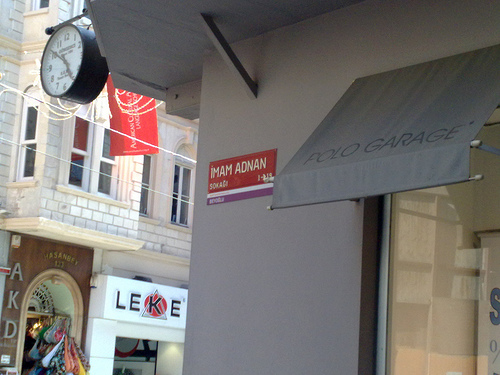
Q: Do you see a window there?
A: Yes, there is a window.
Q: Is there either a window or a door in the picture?
A: Yes, there is a window.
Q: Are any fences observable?
A: No, there are no fences.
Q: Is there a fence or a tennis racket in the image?
A: No, there are no fences or rackets.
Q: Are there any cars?
A: No, there are no cars.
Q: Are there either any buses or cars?
A: No, there are no cars or buses.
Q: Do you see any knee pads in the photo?
A: No, there are no knee pads.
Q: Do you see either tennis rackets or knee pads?
A: No, there are no knee pads or tennis rackets.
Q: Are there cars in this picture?
A: No, there are no cars.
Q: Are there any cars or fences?
A: No, there are no cars or fences.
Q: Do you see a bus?
A: No, there are no buses.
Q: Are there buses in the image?
A: No, there are no buses.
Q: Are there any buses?
A: No, there are no buses.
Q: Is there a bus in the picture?
A: No, there are no buses.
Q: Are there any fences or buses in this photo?
A: No, there are no buses or fences.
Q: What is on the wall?
A: The sign is on the wall.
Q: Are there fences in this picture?
A: No, there are no fences.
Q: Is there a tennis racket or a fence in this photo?
A: No, there are no fences or rackets.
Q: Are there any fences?
A: No, there are no fences.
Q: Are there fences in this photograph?
A: No, there are no fences.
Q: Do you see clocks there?
A: Yes, there is a clock.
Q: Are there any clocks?
A: Yes, there is a clock.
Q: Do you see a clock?
A: Yes, there is a clock.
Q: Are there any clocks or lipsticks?
A: Yes, there is a clock.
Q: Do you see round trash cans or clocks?
A: Yes, there is a round clock.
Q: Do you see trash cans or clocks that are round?
A: Yes, the clock is round.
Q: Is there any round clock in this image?
A: Yes, there is a round clock.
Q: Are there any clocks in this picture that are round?
A: Yes, there is a clock that is round.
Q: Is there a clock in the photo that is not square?
A: Yes, there is a round clock.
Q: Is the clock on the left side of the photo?
A: Yes, the clock is on the left of the image.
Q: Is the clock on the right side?
A: No, the clock is on the left of the image.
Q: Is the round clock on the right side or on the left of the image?
A: The clock is on the left of the image.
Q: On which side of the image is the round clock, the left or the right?
A: The clock is on the left of the image.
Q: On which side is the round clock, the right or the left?
A: The clock is on the left of the image.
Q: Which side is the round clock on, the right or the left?
A: The clock is on the left of the image.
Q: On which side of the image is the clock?
A: The clock is on the left of the image.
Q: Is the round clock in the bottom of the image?
A: No, the clock is in the top of the image.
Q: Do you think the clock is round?
A: Yes, the clock is round.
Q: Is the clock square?
A: No, the clock is round.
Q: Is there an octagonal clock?
A: No, there is a clock but it is round.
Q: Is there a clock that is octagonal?
A: No, there is a clock but it is round.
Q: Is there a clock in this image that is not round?
A: No, there is a clock but it is round.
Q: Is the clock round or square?
A: The clock is round.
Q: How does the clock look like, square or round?
A: The clock is round.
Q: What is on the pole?
A: The clock is on the pole.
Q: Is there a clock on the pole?
A: Yes, there is a clock on the pole.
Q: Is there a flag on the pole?
A: No, there is a clock on the pole.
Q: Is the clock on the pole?
A: Yes, the clock is on the pole.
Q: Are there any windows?
A: Yes, there is a window.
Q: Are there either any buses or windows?
A: Yes, there is a window.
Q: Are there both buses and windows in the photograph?
A: No, there is a window but no buses.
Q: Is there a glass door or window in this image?
A: Yes, there is a glass window.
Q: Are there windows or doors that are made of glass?
A: Yes, the window is made of glass.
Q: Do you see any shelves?
A: No, there are no shelves.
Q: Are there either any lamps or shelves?
A: No, there are no shelves or lamps.